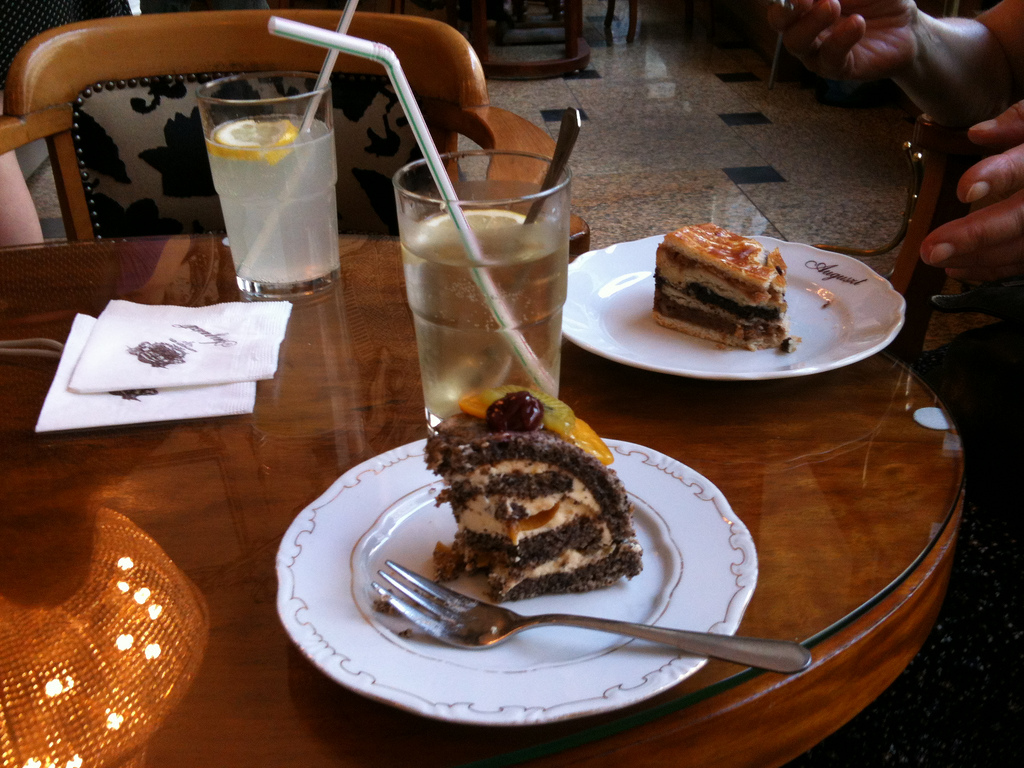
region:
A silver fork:
[371, 559, 812, 676]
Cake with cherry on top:
[425, 385, 641, 600]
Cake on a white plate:
[275, 383, 759, 720]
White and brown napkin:
[68, 297, 291, 389]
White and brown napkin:
[33, 310, 258, 432]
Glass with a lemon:
[196, 64, 345, 306]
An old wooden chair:
[0, 9, 592, 240]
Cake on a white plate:
[563, 224, 906, 377]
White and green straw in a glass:
[264, 15, 571, 433]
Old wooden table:
[0, 233, 971, 766]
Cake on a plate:
[412, 362, 663, 607]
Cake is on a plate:
[400, 373, 644, 602]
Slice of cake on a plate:
[412, 358, 648, 615]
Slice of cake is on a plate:
[419, 377, 653, 605]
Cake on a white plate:
[412, 375, 666, 606]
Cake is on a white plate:
[408, 374, 656, 613]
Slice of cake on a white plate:
[403, 373, 648, 609]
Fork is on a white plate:
[354, 547, 825, 691]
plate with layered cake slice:
[558, 222, 906, 382]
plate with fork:
[269, 396, 811, 725]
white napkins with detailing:
[36, 288, 290, 441]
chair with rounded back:
[5, 4, 575, 243]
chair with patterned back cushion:
[5, 6, 581, 238]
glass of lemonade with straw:
[198, 3, 357, 305]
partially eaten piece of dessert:
[422, 382, 642, 605]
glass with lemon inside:
[196, 67, 346, 303]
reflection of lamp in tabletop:
[5, 241, 957, 766]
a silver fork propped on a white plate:
[275, 431, 808, 722]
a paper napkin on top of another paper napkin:
[38, 295, 291, 433]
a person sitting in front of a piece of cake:
[652, 2, 1014, 767]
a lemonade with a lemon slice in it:
[204, 0, 363, 298]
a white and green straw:
[264, 20, 556, 400]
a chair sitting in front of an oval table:
[1, 12, 969, 759]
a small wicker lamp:
[5, 502, 206, 766]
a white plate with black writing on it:
[566, 224, 906, 381]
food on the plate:
[460, 476, 596, 582]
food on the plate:
[629, 230, 765, 338]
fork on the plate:
[365, 559, 490, 645]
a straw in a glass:
[255, 6, 596, 417]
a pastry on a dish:
[558, 205, 918, 386]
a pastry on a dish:
[259, 377, 773, 745]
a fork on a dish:
[355, 544, 825, 698]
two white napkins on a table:
[25, 279, 309, 444]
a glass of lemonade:
[177, 61, 354, 310]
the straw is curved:
[263, 8, 495, 269]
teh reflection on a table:
[8, 476, 234, 764]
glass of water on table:
[392, 137, 582, 436]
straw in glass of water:
[262, 5, 560, 424]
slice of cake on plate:
[414, 381, 640, 623]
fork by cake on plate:
[352, 548, 831, 695]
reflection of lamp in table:
[3, 477, 218, 766]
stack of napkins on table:
[28, 276, 303, 453]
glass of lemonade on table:
[183, 53, 357, 316]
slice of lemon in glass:
[209, 106, 304, 187]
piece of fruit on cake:
[482, 381, 549, 439]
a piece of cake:
[649, 232, 790, 346]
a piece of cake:
[443, 388, 640, 594]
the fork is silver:
[378, 567, 806, 669]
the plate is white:
[539, 227, 900, 383]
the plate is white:
[280, 435, 751, 717]